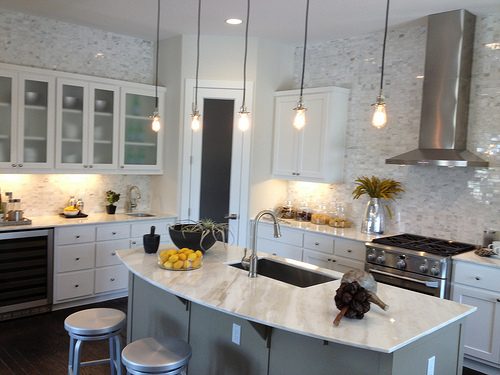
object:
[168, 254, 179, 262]
lemons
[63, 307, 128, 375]
stool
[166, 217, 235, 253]
plant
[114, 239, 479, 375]
counter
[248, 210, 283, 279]
faucet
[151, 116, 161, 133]
lights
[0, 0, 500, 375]
bar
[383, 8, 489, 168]
exhaust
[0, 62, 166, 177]
cupboards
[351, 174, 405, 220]
plant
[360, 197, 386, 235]
pitcher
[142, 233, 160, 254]
bowl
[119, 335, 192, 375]
stools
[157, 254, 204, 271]
bowl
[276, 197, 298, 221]
canisters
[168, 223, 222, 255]
bowl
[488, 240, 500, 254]
cup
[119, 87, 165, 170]
glass doors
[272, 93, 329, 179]
two doors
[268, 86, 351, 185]
cabinet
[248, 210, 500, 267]
countertop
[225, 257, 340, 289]
sink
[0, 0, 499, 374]
kitchen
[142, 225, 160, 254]
mortar and pestle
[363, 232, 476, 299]
oven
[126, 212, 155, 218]
sink